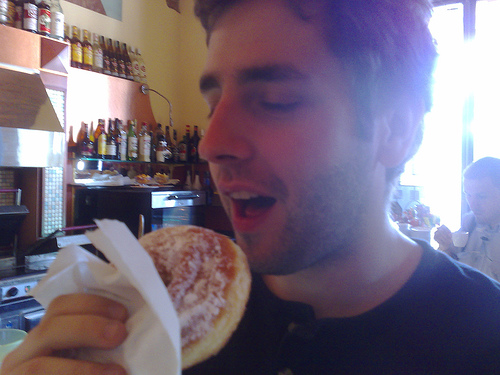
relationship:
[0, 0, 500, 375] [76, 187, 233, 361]
man holding cup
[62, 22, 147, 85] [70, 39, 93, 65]
bottles with labels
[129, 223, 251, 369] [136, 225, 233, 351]
donut covered with sugar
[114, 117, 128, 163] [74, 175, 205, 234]
bottle above oven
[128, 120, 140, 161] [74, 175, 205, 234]
bottle above oven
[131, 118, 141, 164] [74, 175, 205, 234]
bottle above oven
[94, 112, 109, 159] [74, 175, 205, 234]
bottle above oven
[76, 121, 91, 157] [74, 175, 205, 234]
bottle above oven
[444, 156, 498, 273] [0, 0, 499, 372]
patron in restaurant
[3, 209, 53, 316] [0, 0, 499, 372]
oven in restaurant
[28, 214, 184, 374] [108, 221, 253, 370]
napkin on doughnut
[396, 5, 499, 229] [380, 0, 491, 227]
sunlight shining through window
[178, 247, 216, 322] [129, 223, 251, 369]
sugar on donut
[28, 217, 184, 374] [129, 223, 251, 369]
napkin around donut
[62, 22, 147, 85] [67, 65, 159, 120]
bottles around shelf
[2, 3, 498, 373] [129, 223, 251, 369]
man with donut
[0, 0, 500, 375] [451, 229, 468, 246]
man with cup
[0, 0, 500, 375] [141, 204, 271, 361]
man with doughnut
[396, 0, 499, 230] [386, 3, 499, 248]
sunlight in windows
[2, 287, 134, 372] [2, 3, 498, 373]
hand on man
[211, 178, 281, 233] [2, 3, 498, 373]
mouth on man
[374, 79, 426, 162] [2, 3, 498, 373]
ear on man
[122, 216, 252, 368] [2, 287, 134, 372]
doughnut in hand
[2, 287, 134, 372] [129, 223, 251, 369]
hand holding donut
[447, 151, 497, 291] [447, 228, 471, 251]
man holding cup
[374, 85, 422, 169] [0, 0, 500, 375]
ear of man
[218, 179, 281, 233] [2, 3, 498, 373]
mouth of man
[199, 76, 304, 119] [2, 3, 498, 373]
eyes of man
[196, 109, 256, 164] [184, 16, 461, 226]
nose of man